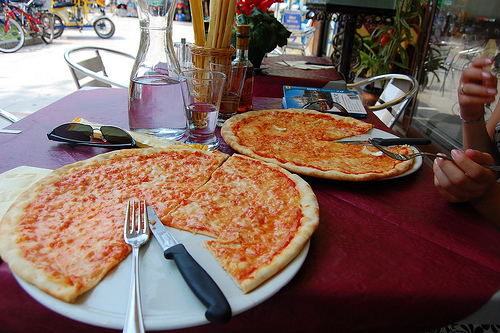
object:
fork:
[122, 195, 154, 333]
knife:
[142, 201, 235, 324]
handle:
[162, 241, 235, 328]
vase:
[124, 1, 193, 143]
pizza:
[2, 142, 330, 309]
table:
[2, 79, 500, 332]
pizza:
[214, 103, 423, 185]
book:
[277, 78, 371, 121]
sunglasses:
[45, 120, 141, 154]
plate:
[6, 229, 318, 331]